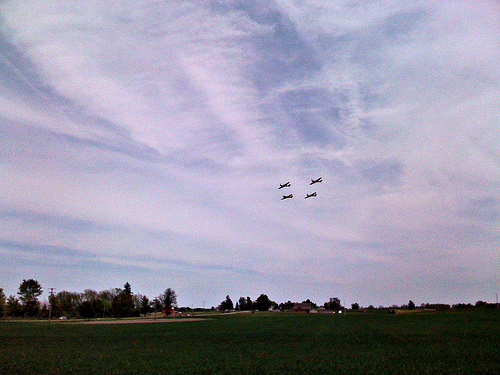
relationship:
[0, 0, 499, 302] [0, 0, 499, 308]
clouds in sky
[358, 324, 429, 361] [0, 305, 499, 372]
grass covering ground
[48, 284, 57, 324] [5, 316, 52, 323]
pole beside road